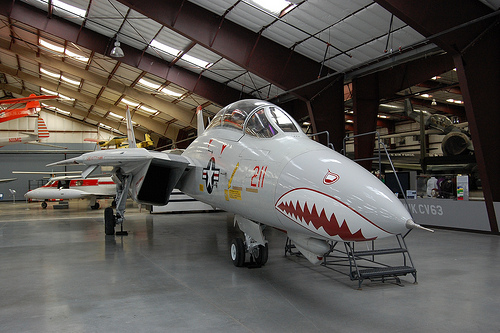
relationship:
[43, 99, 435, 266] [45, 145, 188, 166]
fighter jet has wing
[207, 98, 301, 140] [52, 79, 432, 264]
windshield on plane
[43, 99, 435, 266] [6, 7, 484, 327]
fighter jet on display in hangar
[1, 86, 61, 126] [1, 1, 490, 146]
plane on ceiling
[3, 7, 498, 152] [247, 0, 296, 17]
roof has panel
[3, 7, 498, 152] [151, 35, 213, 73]
roof has panel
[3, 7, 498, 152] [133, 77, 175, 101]
roof has panel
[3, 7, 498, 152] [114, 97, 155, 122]
roof has panel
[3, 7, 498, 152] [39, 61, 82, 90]
roof has panel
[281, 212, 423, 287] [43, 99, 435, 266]
ladder behind fighter jet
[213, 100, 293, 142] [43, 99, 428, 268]
cockpit of fighter jet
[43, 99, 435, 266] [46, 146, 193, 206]
fighter jet has wing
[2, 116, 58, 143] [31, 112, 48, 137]
plane has tail wing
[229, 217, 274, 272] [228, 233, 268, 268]
landing gear has wheels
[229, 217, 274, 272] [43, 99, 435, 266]
landing gear on fighter jet